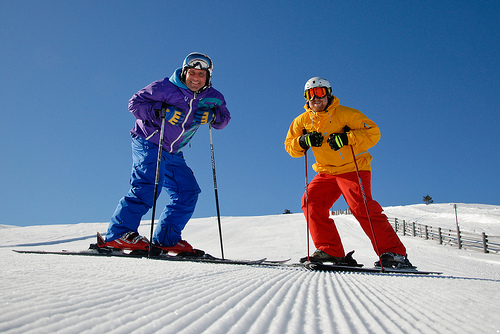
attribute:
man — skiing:
[281, 74, 418, 267]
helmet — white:
[303, 75, 331, 92]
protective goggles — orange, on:
[303, 84, 332, 102]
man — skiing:
[109, 40, 239, 256]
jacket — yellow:
[278, 102, 382, 174]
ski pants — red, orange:
[297, 166, 397, 259]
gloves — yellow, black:
[300, 128, 347, 153]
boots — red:
[102, 227, 199, 250]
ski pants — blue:
[116, 136, 209, 239]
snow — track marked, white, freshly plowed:
[3, 187, 492, 332]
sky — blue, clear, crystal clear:
[3, 2, 500, 214]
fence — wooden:
[386, 202, 500, 261]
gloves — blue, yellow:
[163, 102, 213, 131]